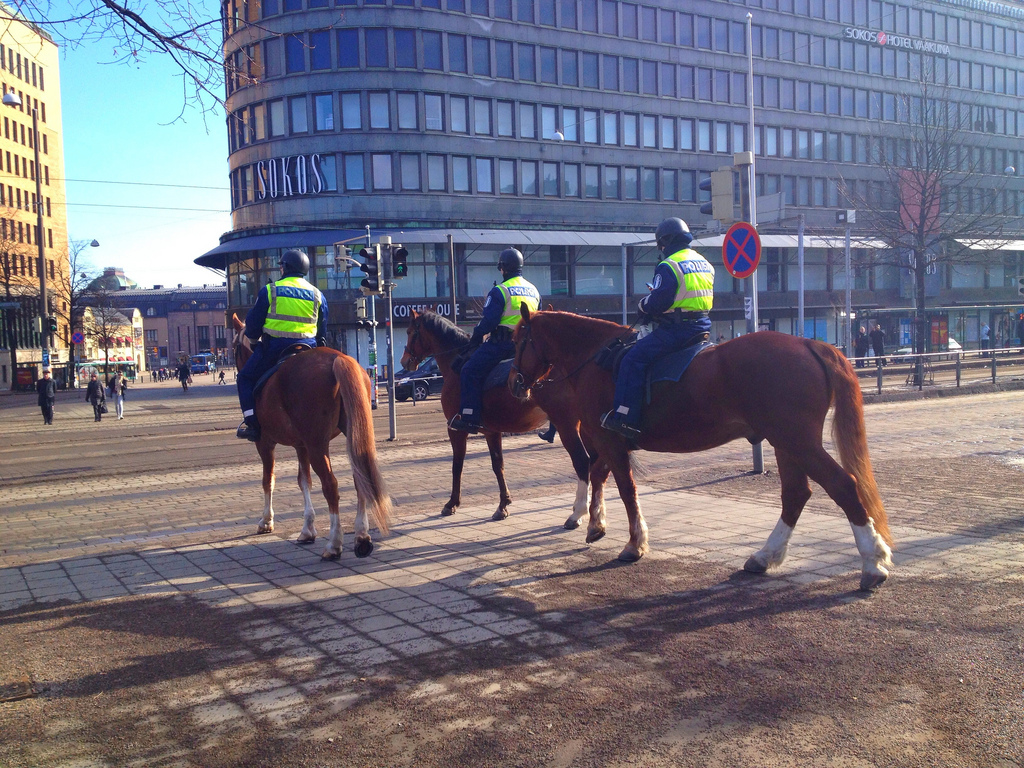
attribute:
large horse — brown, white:
[501, 304, 897, 598]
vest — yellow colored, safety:
[222, 231, 385, 348]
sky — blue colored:
[3, 0, 232, 291]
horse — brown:
[192, 325, 411, 579]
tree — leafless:
[856, 74, 1022, 495]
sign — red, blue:
[697, 216, 777, 287]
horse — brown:
[394, 304, 554, 527]